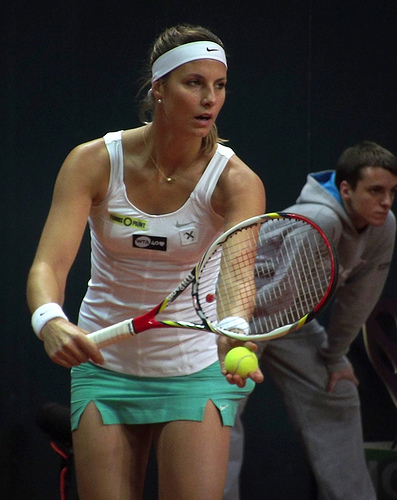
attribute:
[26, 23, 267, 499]
player — athletic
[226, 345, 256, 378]
ball — tennis, here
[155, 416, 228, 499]
leg — bare